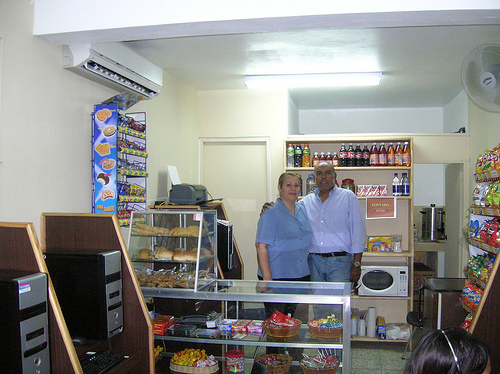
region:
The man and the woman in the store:
[239, 162, 381, 289]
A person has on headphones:
[388, 302, 490, 371]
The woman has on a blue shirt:
[251, 195, 318, 282]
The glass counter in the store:
[152, 273, 362, 368]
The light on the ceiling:
[236, 66, 397, 92]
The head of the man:
[312, 159, 337, 195]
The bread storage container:
[121, 195, 223, 293]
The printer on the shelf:
[160, 160, 216, 206]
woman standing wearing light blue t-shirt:
[257, 171, 312, 363]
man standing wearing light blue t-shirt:
[297, 163, 368, 284]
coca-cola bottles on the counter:
[340, 141, 370, 168]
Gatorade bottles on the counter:
[285, 138, 310, 168]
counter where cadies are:
[129, 276, 348, 370]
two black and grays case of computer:
[0, 245, 125, 371]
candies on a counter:
[152, 307, 343, 372]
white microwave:
[356, 264, 408, 296]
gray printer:
[168, 183, 208, 208]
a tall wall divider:
[39, 206, 161, 372]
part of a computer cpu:
[32, 240, 127, 340]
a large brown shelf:
[283, 138, 418, 350]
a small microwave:
[353, 265, 410, 299]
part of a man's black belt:
[315, 247, 347, 257]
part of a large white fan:
[457, 45, 499, 114]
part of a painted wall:
[195, 90, 282, 135]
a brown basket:
[264, 315, 303, 337]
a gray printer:
[164, 178, 210, 204]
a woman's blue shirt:
[253, 200, 315, 280]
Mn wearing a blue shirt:
[297, 150, 372, 299]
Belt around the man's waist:
[310, 241, 351, 263]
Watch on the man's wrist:
[347, 252, 365, 274]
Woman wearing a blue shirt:
[258, 163, 318, 283]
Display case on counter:
[125, 198, 221, 298]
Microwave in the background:
[349, 257, 413, 298]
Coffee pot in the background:
[418, 188, 450, 242]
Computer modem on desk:
[43, 231, 138, 353]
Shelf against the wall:
[87, 84, 163, 228]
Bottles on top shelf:
[283, 131, 414, 178]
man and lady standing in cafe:
[235, 156, 385, 329]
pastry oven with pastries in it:
[118, 198, 228, 308]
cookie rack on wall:
[72, 82, 168, 248]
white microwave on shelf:
[351, 238, 422, 323]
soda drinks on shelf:
[282, 132, 425, 182]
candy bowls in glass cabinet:
[153, 305, 356, 372]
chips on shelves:
[432, 140, 499, 352]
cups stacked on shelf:
[350, 302, 422, 357]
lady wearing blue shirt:
[252, 164, 320, 288]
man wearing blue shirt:
[286, 167, 368, 283]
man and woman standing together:
[244, 146, 381, 303]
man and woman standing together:
[246, 142, 375, 314]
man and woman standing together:
[239, 145, 389, 308]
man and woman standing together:
[246, 152, 371, 300]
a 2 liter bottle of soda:
[338, 142, 346, 167]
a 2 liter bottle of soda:
[345, 144, 352, 165]